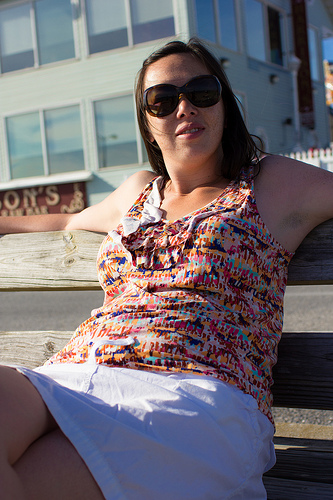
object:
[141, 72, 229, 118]
sunglasses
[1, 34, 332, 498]
girl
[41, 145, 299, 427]
tank top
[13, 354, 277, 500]
mini-skirt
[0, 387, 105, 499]
thigh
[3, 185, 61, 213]
letter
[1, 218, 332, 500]
bench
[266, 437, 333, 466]
slat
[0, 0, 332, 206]
building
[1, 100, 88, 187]
window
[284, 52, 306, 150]
lamppost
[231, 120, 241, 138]
hair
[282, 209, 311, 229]
armpit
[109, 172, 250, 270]
ruffle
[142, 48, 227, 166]
face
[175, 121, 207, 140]
mouth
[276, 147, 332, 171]
fence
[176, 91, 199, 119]
nose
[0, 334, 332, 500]
shadow